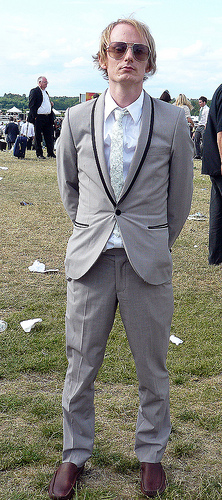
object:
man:
[28, 77, 58, 156]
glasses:
[108, 41, 151, 63]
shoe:
[47, 460, 79, 500]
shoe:
[138, 459, 167, 497]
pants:
[62, 245, 175, 469]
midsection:
[80, 204, 150, 253]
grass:
[0, 148, 222, 455]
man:
[49, 20, 195, 500]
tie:
[110, 107, 128, 240]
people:
[201, 84, 222, 260]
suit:
[27, 87, 56, 159]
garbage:
[20, 316, 46, 332]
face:
[107, 22, 149, 84]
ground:
[0, 151, 222, 498]